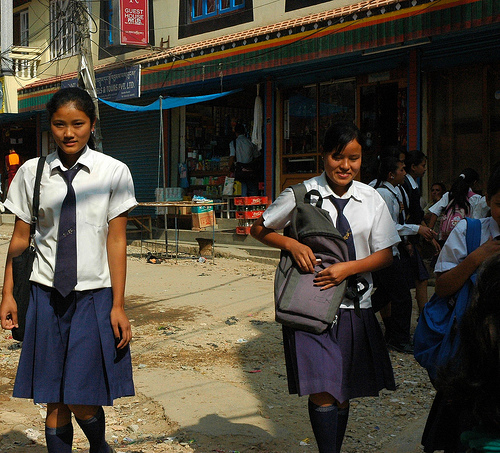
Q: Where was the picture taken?
A: In a city.